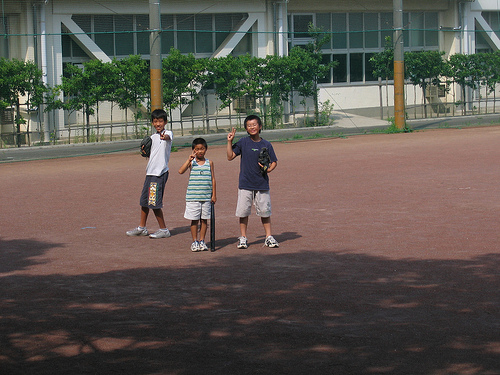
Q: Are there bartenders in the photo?
A: No, there are no bartenders.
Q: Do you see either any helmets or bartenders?
A: No, there are no bartenders or helmets.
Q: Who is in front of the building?
A: The boy is in front of the building.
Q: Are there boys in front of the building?
A: Yes, there is a boy in front of the building.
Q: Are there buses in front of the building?
A: No, there is a boy in front of the building.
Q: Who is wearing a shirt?
A: The boy is wearing a shirt.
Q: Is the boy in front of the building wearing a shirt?
A: Yes, the boy is wearing a shirt.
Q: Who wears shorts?
A: The boy wears shorts.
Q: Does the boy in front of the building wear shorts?
A: Yes, the boy wears shorts.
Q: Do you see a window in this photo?
A: Yes, there is a window.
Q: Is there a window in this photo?
A: Yes, there is a window.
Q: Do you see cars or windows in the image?
A: Yes, there is a window.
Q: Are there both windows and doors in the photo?
A: No, there is a window but no doors.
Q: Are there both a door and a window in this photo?
A: No, there is a window but no doors.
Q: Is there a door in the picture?
A: No, there are no doors.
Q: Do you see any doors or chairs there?
A: No, there are no doors or chairs.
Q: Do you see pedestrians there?
A: No, there are no pedestrians.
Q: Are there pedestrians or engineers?
A: No, there are no pedestrians or engineers.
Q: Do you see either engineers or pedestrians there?
A: No, there are no pedestrians or engineers.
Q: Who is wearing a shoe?
A: The boy is wearing a shoe.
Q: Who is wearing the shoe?
A: The boy is wearing a shoe.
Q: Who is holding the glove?
A: The boy is holding the glove.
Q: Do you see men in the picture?
A: No, there are no men.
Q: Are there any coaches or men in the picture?
A: No, there are no men or coaches.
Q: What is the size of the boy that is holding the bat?
A: The boy is small.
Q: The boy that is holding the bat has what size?
A: The boy is small.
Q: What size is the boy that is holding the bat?
A: The boy is small.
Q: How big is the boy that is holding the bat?
A: The boy is small.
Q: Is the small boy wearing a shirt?
A: Yes, the boy is wearing a shirt.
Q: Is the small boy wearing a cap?
A: No, the boy is wearing a shirt.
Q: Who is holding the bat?
A: The boy is holding the bat.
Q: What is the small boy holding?
A: The boy is holding the bat.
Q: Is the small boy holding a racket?
A: No, the boy is holding the bat.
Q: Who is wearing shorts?
A: The boy is wearing shorts.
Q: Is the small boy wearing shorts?
A: Yes, the boy is wearing shorts.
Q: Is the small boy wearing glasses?
A: No, the boy is wearing shorts.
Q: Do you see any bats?
A: Yes, there is a bat.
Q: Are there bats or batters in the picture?
A: Yes, there is a bat.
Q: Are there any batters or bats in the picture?
A: Yes, there is a bat.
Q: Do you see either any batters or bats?
A: Yes, there is a bat.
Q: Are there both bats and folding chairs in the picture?
A: No, there is a bat but no folding chairs.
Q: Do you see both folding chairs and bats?
A: No, there is a bat but no folding chairs.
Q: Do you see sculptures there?
A: No, there are no sculptures.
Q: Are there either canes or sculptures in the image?
A: No, there are no sculptures or canes.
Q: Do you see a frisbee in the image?
A: No, there are no frisbees.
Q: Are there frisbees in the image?
A: No, there are no frisbees.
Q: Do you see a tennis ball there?
A: No, there are no tennis balls.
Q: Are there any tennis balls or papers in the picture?
A: No, there are no tennis balls or papers.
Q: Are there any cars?
A: No, there are no cars.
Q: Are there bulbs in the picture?
A: No, there are no bulbs.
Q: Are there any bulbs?
A: No, there are no bulbs.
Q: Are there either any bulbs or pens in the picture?
A: No, there are no bulbs or pens.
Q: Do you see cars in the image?
A: No, there are no cars.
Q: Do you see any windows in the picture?
A: Yes, there is a window.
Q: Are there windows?
A: Yes, there is a window.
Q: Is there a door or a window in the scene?
A: Yes, there is a window.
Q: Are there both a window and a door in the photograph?
A: No, there is a window but no doors.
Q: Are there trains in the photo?
A: No, there are no trains.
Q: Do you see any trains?
A: No, there are no trains.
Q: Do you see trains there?
A: No, there are no trains.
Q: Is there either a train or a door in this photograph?
A: No, there are no trains or doors.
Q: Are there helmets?
A: No, there are no helmets.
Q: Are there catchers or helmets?
A: No, there are no helmets or catchers.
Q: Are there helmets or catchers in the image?
A: No, there are no helmets or catchers.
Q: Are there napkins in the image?
A: No, there are no napkins.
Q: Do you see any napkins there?
A: No, there are no napkins.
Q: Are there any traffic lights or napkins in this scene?
A: No, there are no napkins or traffic lights.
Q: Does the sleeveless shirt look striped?
A: Yes, the shirt is striped.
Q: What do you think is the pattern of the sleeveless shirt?
A: The shirt is striped.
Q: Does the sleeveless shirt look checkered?
A: No, the shirt is striped.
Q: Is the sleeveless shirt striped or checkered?
A: The shirt is striped.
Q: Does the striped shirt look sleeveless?
A: Yes, the shirt is sleeveless.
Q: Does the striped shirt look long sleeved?
A: No, the shirt is sleeveless.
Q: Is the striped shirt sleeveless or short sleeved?
A: The shirt is sleeveless.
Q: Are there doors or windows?
A: Yes, there is a window.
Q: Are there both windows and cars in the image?
A: No, there is a window but no cars.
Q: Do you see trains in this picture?
A: No, there are no trains.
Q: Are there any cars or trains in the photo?
A: No, there are no trains or cars.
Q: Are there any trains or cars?
A: No, there are no trains or cars.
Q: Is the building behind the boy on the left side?
A: Yes, the building is behind the boy.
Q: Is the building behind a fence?
A: No, the building is behind the boy.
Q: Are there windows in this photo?
A: Yes, there is a window.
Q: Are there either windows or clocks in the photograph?
A: Yes, there is a window.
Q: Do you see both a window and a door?
A: No, there is a window but no doors.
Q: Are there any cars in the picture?
A: No, there are no cars.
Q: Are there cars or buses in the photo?
A: No, there are no cars or buses.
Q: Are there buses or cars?
A: No, there are no cars or buses.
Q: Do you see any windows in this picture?
A: Yes, there is a window.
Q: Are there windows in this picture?
A: Yes, there is a window.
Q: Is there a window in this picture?
A: Yes, there is a window.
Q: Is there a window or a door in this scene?
A: Yes, there is a window.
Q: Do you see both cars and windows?
A: No, there is a window but no cars.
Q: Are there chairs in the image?
A: No, there are no chairs.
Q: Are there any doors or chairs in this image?
A: No, there are no chairs or doors.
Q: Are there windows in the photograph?
A: Yes, there is a window.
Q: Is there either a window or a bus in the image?
A: Yes, there is a window.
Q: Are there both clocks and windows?
A: No, there is a window but no clocks.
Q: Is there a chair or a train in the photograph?
A: No, there are no chairs or trains.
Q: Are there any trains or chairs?
A: No, there are no chairs or trains.